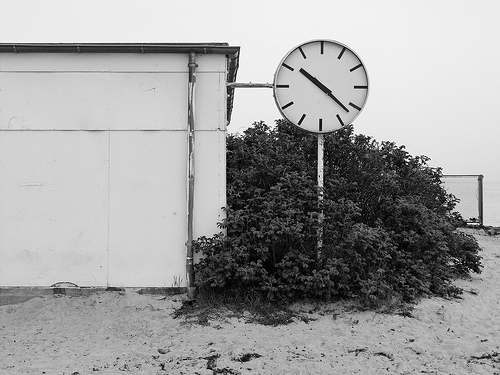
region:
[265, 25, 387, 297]
a white clock on a pole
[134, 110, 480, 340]
a bush next to building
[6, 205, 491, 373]
a dirt ground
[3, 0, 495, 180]
a cloudy sky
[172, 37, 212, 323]
a white and gray pipe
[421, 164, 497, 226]
a gray fence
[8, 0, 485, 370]
a scene outside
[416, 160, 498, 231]
water is seen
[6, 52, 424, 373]
a black and white photo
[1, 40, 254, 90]
gutters on the top of roof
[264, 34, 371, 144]
a black and white clock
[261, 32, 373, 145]
a clock reading 10:21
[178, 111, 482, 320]
a large bush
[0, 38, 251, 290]
a white painted building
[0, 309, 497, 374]
white sand on the ground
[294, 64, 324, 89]
a small clock hand on the ten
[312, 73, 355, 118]
a long clock hand between the four and five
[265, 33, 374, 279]
a clock mounted on a pole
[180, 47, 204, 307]
a rain gutter pipe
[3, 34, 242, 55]
a roof line rain gutter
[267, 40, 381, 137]
a large clock face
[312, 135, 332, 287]
a pole attached to a large clock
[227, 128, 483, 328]
a large bush with a pole in it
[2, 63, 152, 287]
the side of a white building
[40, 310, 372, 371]
sand on a beach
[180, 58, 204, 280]
the water pipe on the side of a building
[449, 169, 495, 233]
a section of fence behind a bush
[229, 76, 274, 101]
a metal piece protruding from the side of a building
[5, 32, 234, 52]
the roofline of the top of a building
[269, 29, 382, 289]
a large metal clock standing inside a bush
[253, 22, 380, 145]
the face of a clock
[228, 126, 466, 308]
overgrown shrubbery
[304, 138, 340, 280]
rusty pole sticking out of the shrubs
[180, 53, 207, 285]
thin pole that's paint is peeling off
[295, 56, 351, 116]
two black clock hands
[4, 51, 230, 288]
white concrete wall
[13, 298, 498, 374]
sandy ground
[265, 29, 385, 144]
clock with thin lines that indicate the time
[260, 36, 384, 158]
white and black clock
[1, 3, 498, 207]
clear skies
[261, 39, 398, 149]
One clock is standing on pole.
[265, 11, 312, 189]
Leaves are green color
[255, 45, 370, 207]
clock is attached to the pole.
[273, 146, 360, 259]
Pole is in between the bush.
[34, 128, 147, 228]
Wall is white color.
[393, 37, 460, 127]
Sky is white color.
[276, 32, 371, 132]
4.23 is the time shown.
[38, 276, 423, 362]
Bushes are in sand.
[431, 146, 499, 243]
Fence is found behind the bush.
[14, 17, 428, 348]
Day time picture.